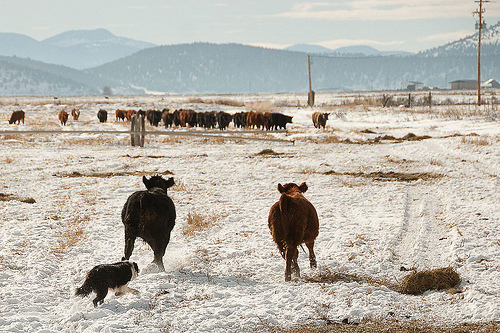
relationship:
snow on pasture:
[5, 96, 499, 332] [3, 87, 489, 328]